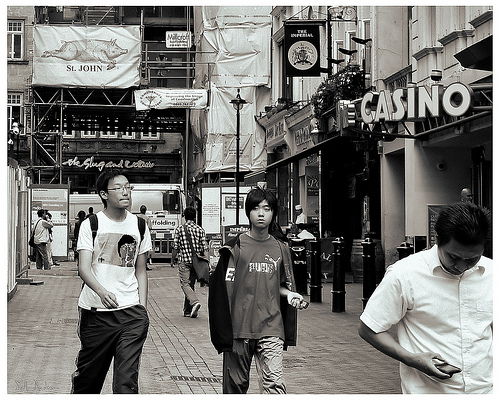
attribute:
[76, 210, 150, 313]
shirt — white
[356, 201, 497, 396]
man — texting, walking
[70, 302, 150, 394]
pants — black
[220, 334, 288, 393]
pants — wrinkled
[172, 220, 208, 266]
shirt — plaid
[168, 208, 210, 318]
person — walking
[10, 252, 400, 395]
street — brick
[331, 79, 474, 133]
sign — large, neon, advertising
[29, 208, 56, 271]
person — standing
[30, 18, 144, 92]
flag — white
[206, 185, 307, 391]
kid — walking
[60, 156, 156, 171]
sign — neon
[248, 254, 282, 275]
logo — white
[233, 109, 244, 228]
lamppost — tall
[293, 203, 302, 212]
hat — white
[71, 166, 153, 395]
person — walking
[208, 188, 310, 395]
person — walking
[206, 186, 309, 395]
man — young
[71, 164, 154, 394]
man — walking